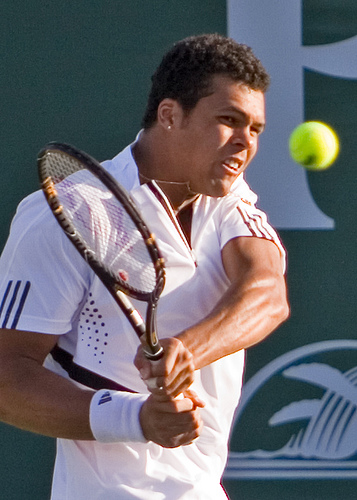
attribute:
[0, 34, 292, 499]
man — playing tennis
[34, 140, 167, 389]
racket — black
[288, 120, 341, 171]
ball — green, blurry, yellow, in the air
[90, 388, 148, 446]
wrist band — white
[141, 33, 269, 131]
hair — curly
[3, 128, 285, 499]
shirt — white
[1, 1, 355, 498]
wall — green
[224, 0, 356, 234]
letter — white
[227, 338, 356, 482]
picture — white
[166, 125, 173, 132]
earring — small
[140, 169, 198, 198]
necklace — gold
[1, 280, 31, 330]
stripes — blue